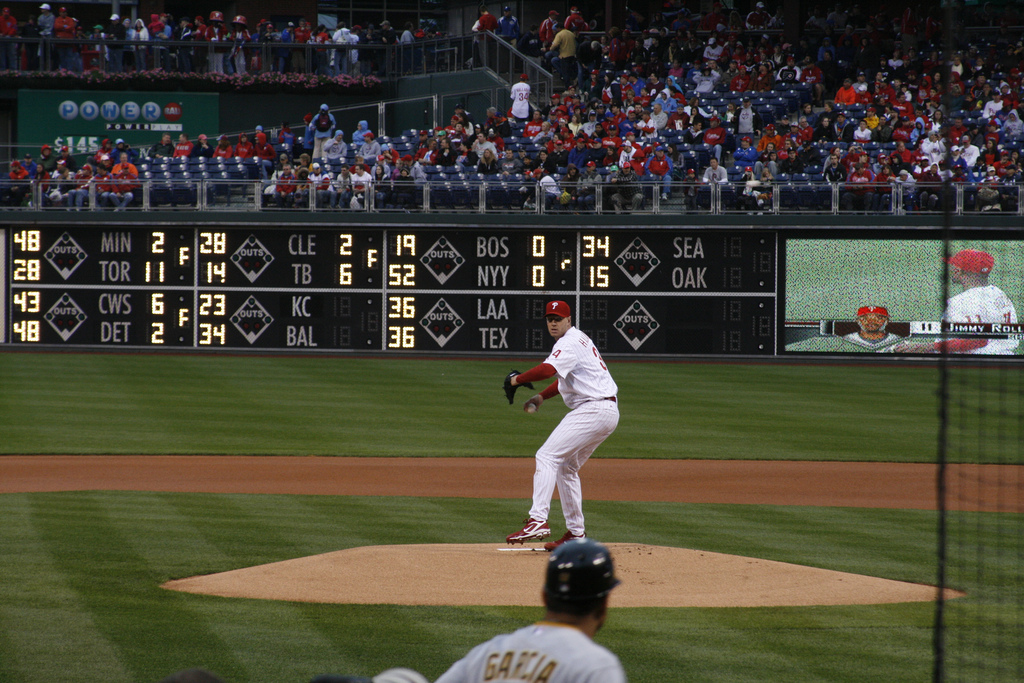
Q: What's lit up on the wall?
A: Scores from other teams.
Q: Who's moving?
A: A player.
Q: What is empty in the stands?
A: Some seats.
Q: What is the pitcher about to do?
A: Throw the ball.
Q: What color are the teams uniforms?
A: White.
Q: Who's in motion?
A: A pitcher.